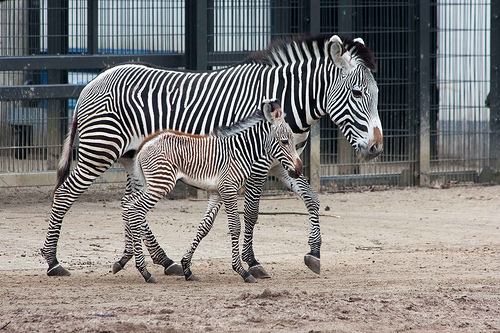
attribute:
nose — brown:
[290, 157, 301, 177]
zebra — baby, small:
[111, 98, 302, 283]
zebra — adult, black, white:
[39, 34, 383, 280]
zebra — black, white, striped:
[90, 70, 382, 137]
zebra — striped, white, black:
[157, 120, 306, 200]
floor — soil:
[16, 187, 498, 329]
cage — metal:
[3, 1, 498, 186]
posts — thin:
[417, 2, 429, 187]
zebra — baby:
[141, 117, 321, 258]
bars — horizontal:
[0, 45, 270, 105]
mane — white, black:
[239, 32, 381, 76]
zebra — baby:
[106, 108, 308, 270]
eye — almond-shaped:
[348, 85, 368, 104]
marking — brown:
[372, 121, 386, 143]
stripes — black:
[122, 75, 144, 134]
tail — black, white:
[48, 101, 78, 193]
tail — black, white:
[131, 157, 143, 190]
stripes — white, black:
[47, 21, 405, 276]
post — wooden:
[415, 2, 437, 191]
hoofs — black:
[45, 265, 71, 279]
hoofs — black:
[109, 260, 121, 273]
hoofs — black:
[145, 277, 159, 283]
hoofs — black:
[164, 262, 185, 275]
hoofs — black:
[301, 254, 323, 276]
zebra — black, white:
[125, 103, 305, 295]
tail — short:
[45, 108, 80, 196]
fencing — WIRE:
[438, 4, 490, 181]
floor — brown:
[206, 229, 461, 309]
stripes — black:
[234, 132, 264, 173]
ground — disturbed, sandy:
[0, 188, 500, 330]